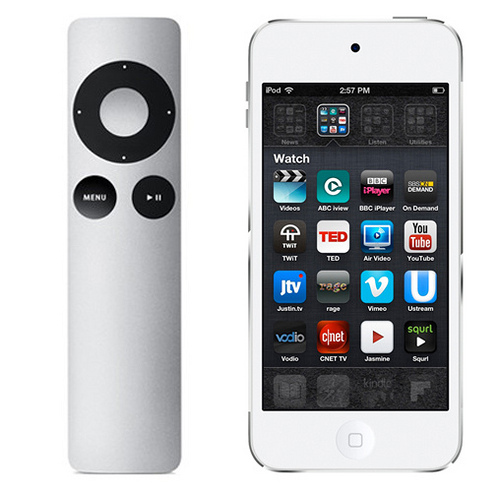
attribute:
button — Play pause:
[128, 172, 191, 220]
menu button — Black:
[70, 174, 117, 217]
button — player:
[133, 174, 177, 219]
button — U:
[399, 269, 440, 310]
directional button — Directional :
[72, 59, 176, 166]